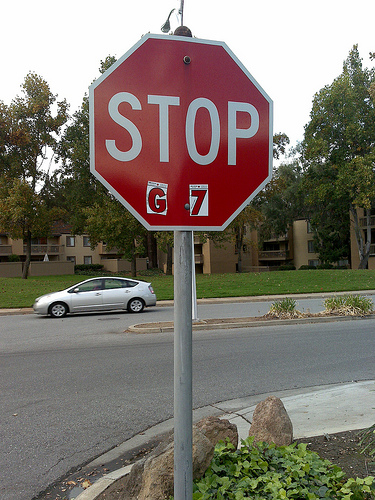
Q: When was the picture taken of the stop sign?
A: Daytime.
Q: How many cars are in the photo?
A: One.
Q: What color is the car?
A: Silver.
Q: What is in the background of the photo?
A: An apartment complex.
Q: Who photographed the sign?
A: A person.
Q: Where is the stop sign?
A: On the side of the street.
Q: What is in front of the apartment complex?
A: Trees.